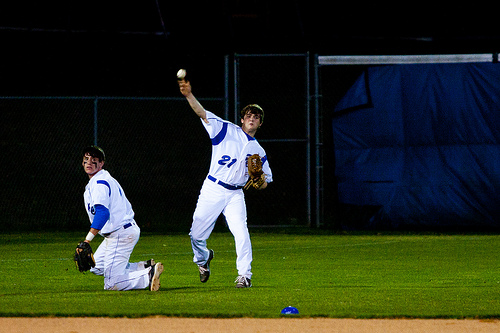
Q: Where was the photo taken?
A: At a baseball game.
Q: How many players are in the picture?
A: Two.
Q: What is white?
A: Player's uniforms.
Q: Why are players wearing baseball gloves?
A: To play baseball.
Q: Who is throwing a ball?
A: Player on right.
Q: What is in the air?
A: Baseball.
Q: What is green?
A: Grass.